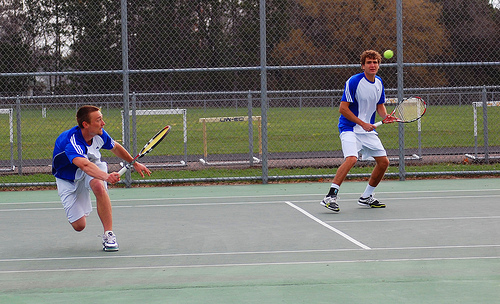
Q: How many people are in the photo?
A: Two.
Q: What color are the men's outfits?
A: Blue and white.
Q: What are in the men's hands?
A: Tennis rackets.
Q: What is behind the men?
A: A fence.